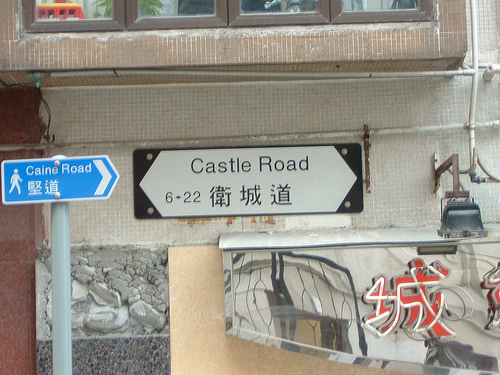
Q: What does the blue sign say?
A: Caine Road.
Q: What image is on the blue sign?
A: A pedestrian.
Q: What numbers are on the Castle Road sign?
A: 622.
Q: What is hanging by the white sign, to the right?
A: A light.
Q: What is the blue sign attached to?
A: A pole.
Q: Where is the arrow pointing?
A: Right.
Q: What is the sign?
A: Blue and white.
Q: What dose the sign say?
A: Castle road.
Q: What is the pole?
A: Metal.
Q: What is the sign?
A: Blue and white.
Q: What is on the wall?
A: Graffiti.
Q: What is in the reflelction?
A: Metal.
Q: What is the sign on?
A: A post.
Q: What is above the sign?
A: Windows.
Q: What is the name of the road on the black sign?
A: Castle Road.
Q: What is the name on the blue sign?
A: Caine Road.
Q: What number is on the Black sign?
A: 6-22.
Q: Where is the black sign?
A: On the building.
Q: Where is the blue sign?
A: On a pole.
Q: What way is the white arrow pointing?
A: To the right.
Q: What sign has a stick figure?
A: The blue one.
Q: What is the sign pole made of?
A: Metal.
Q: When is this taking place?
A: Daytime.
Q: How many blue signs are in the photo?
A: One.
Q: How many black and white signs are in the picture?
A: One.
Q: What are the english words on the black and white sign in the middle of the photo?
A: Castle road.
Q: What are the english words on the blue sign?
A: Caine road.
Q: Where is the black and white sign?
A: Wall.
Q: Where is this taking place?
A: China.